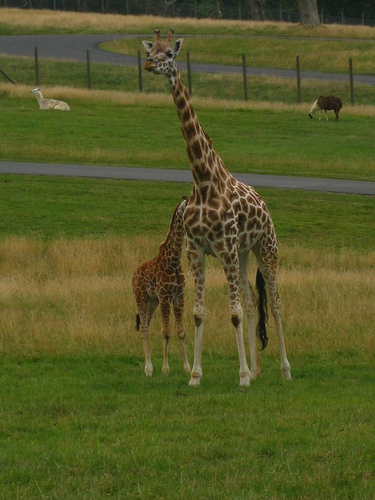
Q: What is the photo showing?
A: It is showing a field.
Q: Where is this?
A: This is at the field.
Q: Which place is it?
A: It is a field.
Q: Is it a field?
A: Yes, it is a field.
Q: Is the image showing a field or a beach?
A: It is showing a field.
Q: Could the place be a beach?
A: No, it is a field.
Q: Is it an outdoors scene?
A: Yes, it is outdoors.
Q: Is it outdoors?
A: Yes, it is outdoors.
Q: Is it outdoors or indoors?
A: It is outdoors.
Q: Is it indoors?
A: No, it is outdoors.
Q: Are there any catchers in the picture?
A: No, there are no catchers.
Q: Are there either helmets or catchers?
A: No, there are no catchers or helmets.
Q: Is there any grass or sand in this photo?
A: Yes, there is grass.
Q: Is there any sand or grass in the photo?
A: Yes, there is grass.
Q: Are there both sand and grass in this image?
A: No, there is grass but no sand.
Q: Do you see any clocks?
A: No, there are no clocks.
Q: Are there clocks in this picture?
A: No, there are no clocks.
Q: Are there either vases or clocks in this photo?
A: No, there are no clocks or vases.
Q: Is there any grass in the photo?
A: Yes, there is grass.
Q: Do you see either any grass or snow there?
A: Yes, there is grass.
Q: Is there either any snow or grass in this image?
A: Yes, there is grass.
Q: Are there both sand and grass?
A: No, there is grass but no sand.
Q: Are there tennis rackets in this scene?
A: No, there are no tennis rackets.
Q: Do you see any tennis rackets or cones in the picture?
A: No, there are no tennis rackets or cones.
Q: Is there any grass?
A: Yes, there is grass.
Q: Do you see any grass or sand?
A: Yes, there is grass.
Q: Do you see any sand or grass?
A: Yes, there is grass.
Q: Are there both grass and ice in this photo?
A: No, there is grass but no ice.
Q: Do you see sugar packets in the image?
A: No, there are no sugar packets.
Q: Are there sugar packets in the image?
A: No, there are no sugar packets.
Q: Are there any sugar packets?
A: No, there are no sugar packets.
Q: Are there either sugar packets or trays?
A: No, there are no sugar packets or trays.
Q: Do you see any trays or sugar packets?
A: No, there are no sugar packets or trays.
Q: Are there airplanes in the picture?
A: No, there are no airplanes.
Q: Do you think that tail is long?
A: Yes, the tail is long.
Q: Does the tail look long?
A: Yes, the tail is long.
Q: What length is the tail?
A: The tail is long.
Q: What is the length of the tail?
A: The tail is long.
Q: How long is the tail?
A: The tail is long.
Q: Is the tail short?
A: No, the tail is long.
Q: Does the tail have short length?
A: No, the tail is long.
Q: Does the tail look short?
A: No, the tail is long.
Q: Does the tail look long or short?
A: The tail is long.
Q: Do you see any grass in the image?
A: Yes, there is grass.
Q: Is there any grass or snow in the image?
A: Yes, there is grass.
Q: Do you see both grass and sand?
A: No, there is grass but no sand.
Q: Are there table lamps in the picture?
A: No, there are no table lamps.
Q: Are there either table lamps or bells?
A: No, there are no table lamps or bells.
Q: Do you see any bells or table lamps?
A: No, there are no table lamps or bells.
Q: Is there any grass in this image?
A: Yes, there is grass.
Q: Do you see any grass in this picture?
A: Yes, there is grass.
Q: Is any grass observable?
A: Yes, there is grass.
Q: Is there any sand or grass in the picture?
A: Yes, there is grass.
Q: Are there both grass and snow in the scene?
A: No, there is grass but no snow.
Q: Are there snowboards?
A: No, there are no snowboards.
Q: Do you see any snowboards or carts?
A: No, there are no snowboards or carts.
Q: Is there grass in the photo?
A: Yes, there is grass.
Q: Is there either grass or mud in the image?
A: Yes, there is grass.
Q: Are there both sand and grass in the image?
A: No, there is grass but no sand.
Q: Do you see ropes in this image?
A: No, there are no ropes.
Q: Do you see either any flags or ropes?
A: No, there are no ropes or flags.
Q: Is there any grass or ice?
A: Yes, there is grass.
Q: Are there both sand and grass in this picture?
A: No, there is grass but no sand.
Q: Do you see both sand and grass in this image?
A: No, there is grass but no sand.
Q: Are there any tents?
A: No, there are no tents.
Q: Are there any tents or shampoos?
A: No, there are no tents or shampoos.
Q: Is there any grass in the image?
A: Yes, there is grass.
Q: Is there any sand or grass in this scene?
A: Yes, there is grass.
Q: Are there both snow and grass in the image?
A: No, there is grass but no snow.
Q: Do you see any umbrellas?
A: No, there are no umbrellas.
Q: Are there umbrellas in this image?
A: No, there are no umbrellas.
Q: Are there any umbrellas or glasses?
A: No, there are no umbrellas or glasses.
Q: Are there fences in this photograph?
A: Yes, there is a fence.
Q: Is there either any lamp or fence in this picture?
A: Yes, there is a fence.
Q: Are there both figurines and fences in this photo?
A: No, there is a fence but no figurines.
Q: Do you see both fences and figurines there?
A: No, there is a fence but no figurines.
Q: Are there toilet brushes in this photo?
A: No, there are no toilet brushes.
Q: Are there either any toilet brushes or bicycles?
A: No, there are no toilet brushes or bicycles.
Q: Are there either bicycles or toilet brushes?
A: No, there are no toilet brushes or bicycles.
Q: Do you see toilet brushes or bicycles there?
A: No, there are no toilet brushes or bicycles.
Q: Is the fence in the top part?
A: Yes, the fence is in the top of the image.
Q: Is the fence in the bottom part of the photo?
A: No, the fence is in the top of the image.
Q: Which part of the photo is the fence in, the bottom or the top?
A: The fence is in the top of the image.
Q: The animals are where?
A: The animals are in the field.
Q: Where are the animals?
A: The animals are in the field.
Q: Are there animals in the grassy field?
A: Yes, there are animals in the field.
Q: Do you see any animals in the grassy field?
A: Yes, there are animals in the field.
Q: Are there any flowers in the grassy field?
A: No, there are animals in the field.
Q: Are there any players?
A: No, there are no players.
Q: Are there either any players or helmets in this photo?
A: No, there are no players or helmets.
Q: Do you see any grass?
A: Yes, there is grass.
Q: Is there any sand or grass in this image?
A: Yes, there is grass.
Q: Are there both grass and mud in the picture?
A: No, there is grass but no mud.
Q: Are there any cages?
A: No, there are no cages.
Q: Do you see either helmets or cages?
A: No, there are no cages or helmets.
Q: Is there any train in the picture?
A: No, there are no trains.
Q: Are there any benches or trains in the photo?
A: No, there are no trains or benches.